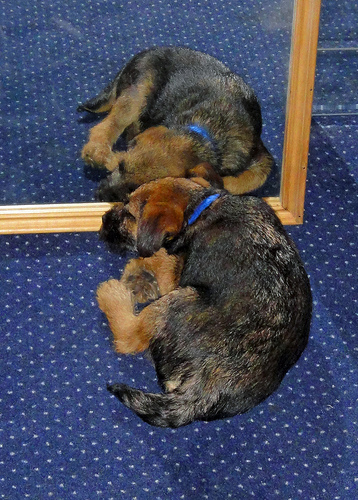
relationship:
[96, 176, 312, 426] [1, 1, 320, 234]
dog in front of mirror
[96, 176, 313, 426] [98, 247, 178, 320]
dog has paws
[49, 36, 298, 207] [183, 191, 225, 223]
dog has collar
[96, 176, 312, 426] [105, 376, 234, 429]
dog has tail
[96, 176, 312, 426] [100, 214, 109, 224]
dog has nose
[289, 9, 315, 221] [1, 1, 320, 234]
frame around mirror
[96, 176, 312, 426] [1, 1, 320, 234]
dog curled up in front of mirror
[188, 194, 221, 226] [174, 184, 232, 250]
collar around neck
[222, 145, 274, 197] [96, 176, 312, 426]
skin behind dog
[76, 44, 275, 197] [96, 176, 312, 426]
reflection of dog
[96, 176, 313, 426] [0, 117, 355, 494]
dog laying on floor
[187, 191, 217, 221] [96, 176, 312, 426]
collar on dog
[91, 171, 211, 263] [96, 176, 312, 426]
head of dog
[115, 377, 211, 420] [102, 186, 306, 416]
tail of dog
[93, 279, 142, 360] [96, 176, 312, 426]
leg of dog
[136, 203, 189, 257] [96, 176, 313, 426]
ear of dog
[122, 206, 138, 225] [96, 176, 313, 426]
left eye of dog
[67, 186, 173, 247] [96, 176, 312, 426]
mouth of dog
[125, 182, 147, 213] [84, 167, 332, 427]
forehead of dog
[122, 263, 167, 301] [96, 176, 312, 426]
left paw of dog